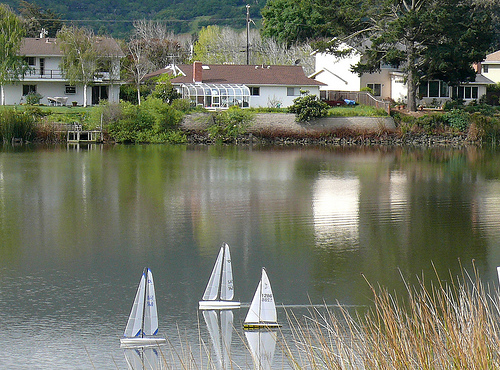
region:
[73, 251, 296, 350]
Sailboats in the water.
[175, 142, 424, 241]
The water is calm.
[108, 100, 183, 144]
Trees on the side of the water.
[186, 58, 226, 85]
The chimney on top of the roof.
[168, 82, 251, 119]
A enclosed screen patio.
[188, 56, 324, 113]
House by the river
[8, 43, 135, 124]
The house is two stories.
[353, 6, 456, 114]
Tree next to the house.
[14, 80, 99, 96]
Windows on the house.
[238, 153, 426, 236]
Reflection in the water.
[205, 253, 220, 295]
sail on the boat.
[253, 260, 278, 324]
boat in the water.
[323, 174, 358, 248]
reflection in the water.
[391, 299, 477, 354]
grass near the water.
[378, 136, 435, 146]
rocks near the water.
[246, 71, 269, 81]
roof on the house.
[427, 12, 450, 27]
leaves on the tree.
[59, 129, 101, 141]
dock near the water.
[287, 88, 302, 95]
window on the house.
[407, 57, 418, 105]
trunk of the tree.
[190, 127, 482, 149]
rocky edge of the water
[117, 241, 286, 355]
three toy sailboats on the water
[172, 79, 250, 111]
greenhouse in a backyard near the water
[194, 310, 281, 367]
reflection of two toy sailboats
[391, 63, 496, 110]
porch on a white house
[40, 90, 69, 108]
backyard barbeque with a cover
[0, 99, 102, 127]
green yard near the water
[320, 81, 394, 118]
wooden fence between properties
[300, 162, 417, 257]
reflection of white house off the water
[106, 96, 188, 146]
bushes at edge of water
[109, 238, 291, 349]
three toy sailboats in a pond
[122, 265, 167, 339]
white sails of toy sailboat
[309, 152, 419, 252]
reflection of house on water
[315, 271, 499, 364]
tall brown grass at water's edge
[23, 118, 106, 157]
brown wooden dock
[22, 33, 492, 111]
houses along a pond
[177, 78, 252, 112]
glass porch attached to house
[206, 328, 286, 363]
sailboat sails reflected in water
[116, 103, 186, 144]
green bushes along the waters edge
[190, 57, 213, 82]
brick chimney on top of house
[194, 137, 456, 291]
the water is still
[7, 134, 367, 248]
the water is calm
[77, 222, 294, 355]
3 sailboats are on the water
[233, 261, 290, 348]
the sail is white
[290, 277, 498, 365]
the grass is high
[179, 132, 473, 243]
the water is reflecting objects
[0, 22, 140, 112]
the house is white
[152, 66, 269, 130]
the deck is made of glass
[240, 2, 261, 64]
the light is off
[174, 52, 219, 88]
the chimney is made of brick